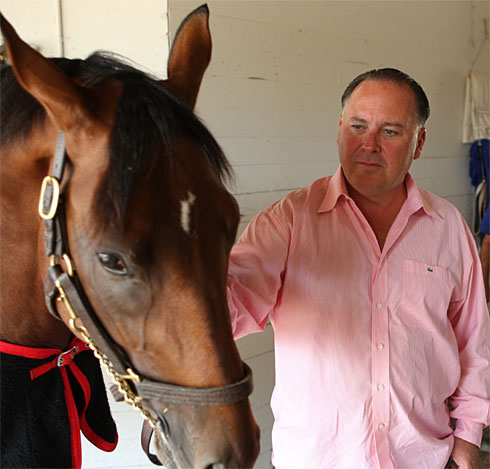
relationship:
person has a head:
[226, 68, 489, 469] [337, 65, 428, 188]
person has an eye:
[226, 68, 489, 469] [352, 124, 369, 129]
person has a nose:
[226, 68, 489, 469] [362, 129, 383, 153]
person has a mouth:
[226, 68, 489, 469] [358, 160, 385, 170]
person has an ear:
[226, 68, 489, 469] [416, 128, 427, 156]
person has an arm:
[226, 68, 489, 469] [228, 199, 285, 337]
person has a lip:
[226, 68, 489, 469] [356, 160, 383, 166]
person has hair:
[226, 68, 489, 469] [341, 68, 430, 123]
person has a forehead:
[226, 68, 489, 469] [347, 79, 415, 124]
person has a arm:
[226, 68, 489, 469] [228, 199, 285, 337]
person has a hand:
[226, 68, 489, 469] [452, 438, 481, 468]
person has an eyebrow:
[226, 68, 489, 469] [350, 115, 367, 123]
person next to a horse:
[226, 68, 489, 469] [3, 2, 259, 468]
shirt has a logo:
[228, 163, 489, 467] [425, 267, 433, 276]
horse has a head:
[3, 2, 259, 468] [337, 65, 428, 188]